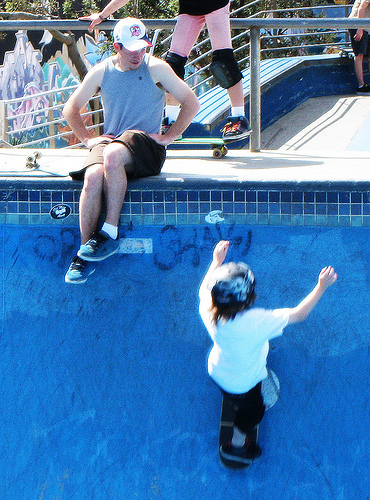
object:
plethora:
[98, 0, 251, 82]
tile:
[232, 190, 245, 204]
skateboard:
[0, 151, 68, 176]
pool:
[0, 181, 370, 500]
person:
[348, 0, 370, 96]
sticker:
[50, 204, 72, 220]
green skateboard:
[171, 130, 253, 159]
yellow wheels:
[213, 146, 228, 159]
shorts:
[69, 130, 166, 182]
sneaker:
[65, 249, 97, 284]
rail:
[0, 18, 370, 33]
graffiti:
[32, 223, 252, 270]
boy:
[199, 239, 338, 469]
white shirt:
[199, 307, 290, 393]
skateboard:
[218, 369, 280, 471]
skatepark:
[0, 0, 370, 182]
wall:
[0, 185, 370, 500]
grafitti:
[30, 227, 76, 267]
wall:
[0, 253, 197, 384]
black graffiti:
[153, 220, 252, 271]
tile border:
[0, 181, 370, 225]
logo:
[130, 24, 141, 37]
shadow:
[229, 157, 324, 169]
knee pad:
[209, 49, 243, 89]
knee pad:
[165, 51, 188, 81]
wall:
[38, 182, 356, 282]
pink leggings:
[169, 1, 233, 57]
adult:
[62, 17, 200, 285]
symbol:
[137, 75, 142, 82]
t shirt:
[99, 56, 166, 138]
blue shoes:
[65, 227, 120, 284]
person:
[164, 0, 253, 159]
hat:
[114, 17, 153, 52]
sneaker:
[76, 229, 120, 261]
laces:
[71, 256, 87, 272]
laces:
[87, 231, 109, 248]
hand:
[78, 13, 105, 32]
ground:
[0, 144, 370, 180]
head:
[211, 261, 255, 316]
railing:
[0, 18, 370, 151]